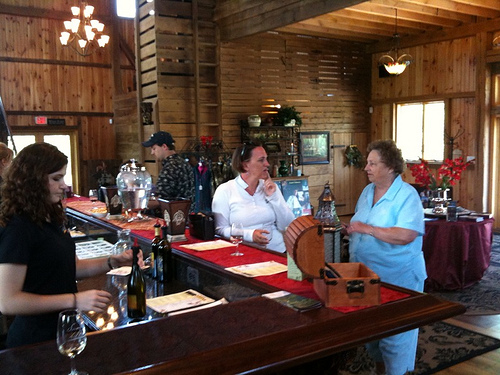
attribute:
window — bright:
[386, 92, 456, 169]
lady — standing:
[342, 134, 426, 364]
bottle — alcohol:
[121, 237, 148, 324]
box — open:
[283, 213, 383, 314]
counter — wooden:
[44, 178, 479, 371]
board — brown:
[139, 84, 160, 105]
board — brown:
[137, 66, 159, 82]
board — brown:
[140, 56, 160, 72]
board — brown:
[137, 25, 158, 42]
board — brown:
[135, 4, 163, 107]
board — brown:
[134, 0, 161, 22]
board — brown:
[285, 218, 317, 273]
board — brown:
[298, 212, 323, 234]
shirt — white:
[214, 175, 297, 249]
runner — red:
[64, 180, 424, 332]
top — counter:
[5, 178, 458, 373]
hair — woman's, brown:
[4, 136, 80, 237]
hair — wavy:
[1, 134, 69, 241]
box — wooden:
[284, 217, 387, 317]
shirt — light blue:
[351, 174, 436, 287]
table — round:
[421, 192, 499, 295]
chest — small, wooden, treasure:
[275, 211, 395, 317]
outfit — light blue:
[350, 177, 428, 370]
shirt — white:
[208, 171, 293, 254]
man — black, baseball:
[147, 122, 205, 222]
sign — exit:
[26, 112, 57, 132]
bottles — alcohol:
[135, 218, 189, 304]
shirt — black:
[3, 203, 89, 342]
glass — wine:
[57, 305, 98, 370]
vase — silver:
[409, 150, 471, 225]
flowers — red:
[398, 150, 468, 200]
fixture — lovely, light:
[370, 42, 436, 82]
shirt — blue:
[349, 190, 428, 280]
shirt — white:
[215, 171, 285, 248]